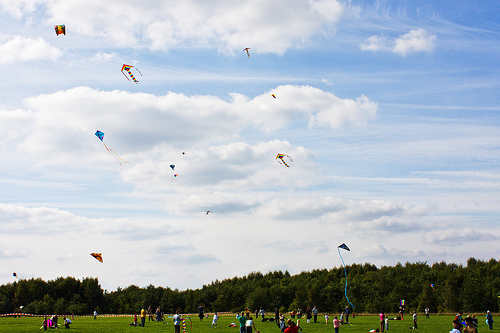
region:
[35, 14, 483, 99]
the sky is cloudy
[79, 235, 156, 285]
kites are in the sky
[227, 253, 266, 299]
the grass is in the background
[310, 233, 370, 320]
the kites are flying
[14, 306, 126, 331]
a yellow and red fence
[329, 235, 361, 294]
the kite is blue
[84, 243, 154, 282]
the kite is red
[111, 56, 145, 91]
kite with a long tail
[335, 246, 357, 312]
long green tail on kite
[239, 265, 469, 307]
trees behind the field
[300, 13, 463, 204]
blue sky streaked with white clouds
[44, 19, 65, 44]
large kite in the sky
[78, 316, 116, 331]
green grass of the field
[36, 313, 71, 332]
people putting a kite together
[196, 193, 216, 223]
kite is barely visible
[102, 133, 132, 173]
long red tail of kite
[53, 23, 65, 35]
the kite is in the air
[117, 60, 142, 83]
the kite is in mid air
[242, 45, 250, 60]
the kite is flying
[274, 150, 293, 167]
the kite is flying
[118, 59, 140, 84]
the kite is flying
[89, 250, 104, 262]
the kite is in mid air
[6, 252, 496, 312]
a forrest is in the distance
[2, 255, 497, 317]
trees are in the distance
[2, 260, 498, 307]
the trees are full of leaves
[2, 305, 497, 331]
the field is full of grass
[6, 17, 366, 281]
many kites in the sky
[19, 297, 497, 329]
crowd of people in a park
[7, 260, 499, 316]
trees border the park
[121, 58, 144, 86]
a kite shaped like an arrow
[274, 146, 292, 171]
a kite with two long tails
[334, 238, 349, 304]
a kite with a long green tail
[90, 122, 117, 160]
a blue kite with an orange tail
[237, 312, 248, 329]
a person in a green top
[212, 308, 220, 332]
a person flies a kite dressed all in white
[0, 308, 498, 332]
ground covered in green grass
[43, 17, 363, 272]
several kites in the sky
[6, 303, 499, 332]
large group of people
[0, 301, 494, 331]
people on the grass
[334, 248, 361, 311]
long blue tail hanging down from the kite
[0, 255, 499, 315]
row of dark green trees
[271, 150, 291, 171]
kite flying by the clouds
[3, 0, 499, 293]
thick white clouds in the sky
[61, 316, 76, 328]
person crouching in the grass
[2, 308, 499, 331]
bright green grass on the ground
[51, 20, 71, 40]
kite flying high